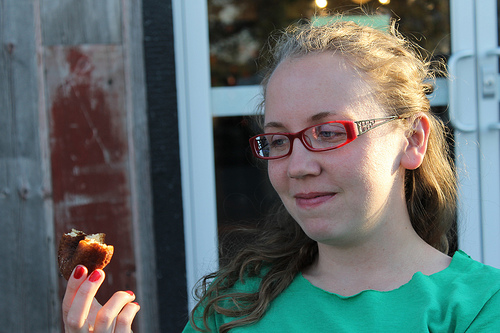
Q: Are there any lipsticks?
A: No, there are no lipsticks.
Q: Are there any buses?
A: No, there are no buses.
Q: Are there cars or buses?
A: No, there are no buses or cars.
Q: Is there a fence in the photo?
A: No, there are no fences.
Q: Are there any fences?
A: No, there are no fences.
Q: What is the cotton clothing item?
A: The clothing item is a shirt.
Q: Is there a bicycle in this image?
A: No, there are no bicycles.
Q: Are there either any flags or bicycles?
A: No, there are no bicycles or flags.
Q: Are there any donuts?
A: Yes, there is a donut.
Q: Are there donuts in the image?
A: Yes, there is a donut.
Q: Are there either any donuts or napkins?
A: Yes, there is a donut.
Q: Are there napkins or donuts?
A: Yes, there is a donut.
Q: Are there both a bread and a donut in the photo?
A: No, there is a donut but no breads.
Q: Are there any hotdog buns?
A: No, there are no hotdog buns.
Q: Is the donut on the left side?
A: Yes, the donut is on the left of the image.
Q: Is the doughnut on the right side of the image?
A: No, the doughnut is on the left of the image.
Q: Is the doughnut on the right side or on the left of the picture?
A: The doughnut is on the left of the image.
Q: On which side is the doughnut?
A: The doughnut is on the left of the image.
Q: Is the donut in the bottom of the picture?
A: Yes, the donut is in the bottom of the image.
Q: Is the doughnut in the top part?
A: No, the doughnut is in the bottom of the image.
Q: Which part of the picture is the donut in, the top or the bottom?
A: The donut is in the bottom of the image.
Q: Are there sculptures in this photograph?
A: No, there are no sculptures.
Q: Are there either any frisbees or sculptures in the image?
A: No, there are no sculptures or frisbees.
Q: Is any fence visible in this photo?
A: No, there are no fences.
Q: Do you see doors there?
A: Yes, there is a door.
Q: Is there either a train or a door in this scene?
A: Yes, there is a door.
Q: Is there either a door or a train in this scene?
A: Yes, there is a door.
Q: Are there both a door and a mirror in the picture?
A: No, there is a door but no mirrors.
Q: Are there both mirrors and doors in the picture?
A: No, there is a door but no mirrors.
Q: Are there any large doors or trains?
A: Yes, there is a large door.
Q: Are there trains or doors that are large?
A: Yes, the door is large.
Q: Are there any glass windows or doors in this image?
A: Yes, there is a glass door.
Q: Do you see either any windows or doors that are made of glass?
A: Yes, the door is made of glass.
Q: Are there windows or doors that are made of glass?
A: Yes, the door is made of glass.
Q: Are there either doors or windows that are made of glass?
A: Yes, the door is made of glass.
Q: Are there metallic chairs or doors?
A: Yes, there is a metal door.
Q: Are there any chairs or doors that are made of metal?
A: Yes, the door is made of metal.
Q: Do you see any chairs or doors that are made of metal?
A: Yes, the door is made of metal.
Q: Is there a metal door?
A: Yes, there is a door that is made of metal.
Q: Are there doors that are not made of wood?
A: Yes, there is a door that is made of metal.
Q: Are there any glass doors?
A: Yes, there is a door that is made of glass.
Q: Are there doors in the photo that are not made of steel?
A: Yes, there is a door that is made of glass.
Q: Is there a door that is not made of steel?
A: Yes, there is a door that is made of glass.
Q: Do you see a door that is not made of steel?
A: Yes, there is a door that is made of glass.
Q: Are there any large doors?
A: Yes, there is a large door.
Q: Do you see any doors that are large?
A: Yes, there is a door that is large.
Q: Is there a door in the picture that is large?
A: Yes, there is a door that is large.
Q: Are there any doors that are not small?
A: Yes, there is a large door.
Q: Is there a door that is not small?
A: Yes, there is a large door.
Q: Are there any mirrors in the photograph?
A: No, there are no mirrors.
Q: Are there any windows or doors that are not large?
A: No, there is a door but it is large.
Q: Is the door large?
A: Yes, the door is large.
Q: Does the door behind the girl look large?
A: Yes, the door is large.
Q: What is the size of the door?
A: The door is large.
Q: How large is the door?
A: The door is large.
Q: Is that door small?
A: No, the door is large.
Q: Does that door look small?
A: No, the door is large.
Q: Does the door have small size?
A: No, the door is large.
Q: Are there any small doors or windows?
A: No, there is a door but it is large.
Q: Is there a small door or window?
A: No, there is a door but it is large.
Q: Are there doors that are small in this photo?
A: No, there is a door but it is large.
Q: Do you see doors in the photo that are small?
A: No, there is a door but it is large.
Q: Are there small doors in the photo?
A: No, there is a door but it is large.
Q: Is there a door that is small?
A: No, there is a door but it is large.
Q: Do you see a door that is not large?
A: No, there is a door but it is large.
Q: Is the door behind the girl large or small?
A: The door is large.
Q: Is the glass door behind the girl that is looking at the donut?
A: Yes, the door is behind the girl.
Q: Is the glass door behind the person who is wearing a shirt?
A: Yes, the door is behind the girl.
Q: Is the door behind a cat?
A: No, the door is behind the girl.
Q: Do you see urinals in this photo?
A: No, there are no urinals.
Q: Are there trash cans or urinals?
A: No, there are no urinals or trash cans.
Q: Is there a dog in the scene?
A: No, there are no dogs.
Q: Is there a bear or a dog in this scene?
A: No, there are no dogs or bears.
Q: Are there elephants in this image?
A: No, there are no elephants.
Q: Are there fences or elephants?
A: No, there are no elephants or fences.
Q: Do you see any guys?
A: No, there are no guys.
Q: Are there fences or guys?
A: No, there are no guys or fences.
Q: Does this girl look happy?
A: Yes, the girl is happy.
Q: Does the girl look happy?
A: Yes, the girl is happy.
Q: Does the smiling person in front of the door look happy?
A: Yes, the girl is happy.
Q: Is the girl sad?
A: No, the girl is happy.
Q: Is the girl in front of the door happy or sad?
A: The girl is happy.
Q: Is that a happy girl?
A: Yes, that is a happy girl.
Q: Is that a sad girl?
A: No, that is a happy girl.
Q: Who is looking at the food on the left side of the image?
A: The girl is looking at the donut.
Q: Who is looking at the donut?
A: The girl is looking at the donut.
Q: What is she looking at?
A: The girl is looking at the doughnut.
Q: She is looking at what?
A: The girl is looking at the doughnut.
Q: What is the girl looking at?
A: The girl is looking at the doughnut.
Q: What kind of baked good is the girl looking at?
A: The girl is looking at the donut.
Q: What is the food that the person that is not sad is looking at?
A: The food is a donut.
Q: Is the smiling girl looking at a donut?
A: Yes, the girl is looking at a donut.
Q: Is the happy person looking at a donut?
A: Yes, the girl is looking at a donut.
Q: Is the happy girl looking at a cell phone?
A: No, the girl is looking at a donut.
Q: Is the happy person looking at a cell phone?
A: No, the girl is looking at a donut.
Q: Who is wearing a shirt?
A: The girl is wearing a shirt.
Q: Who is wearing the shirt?
A: The girl is wearing a shirt.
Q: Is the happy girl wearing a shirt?
A: Yes, the girl is wearing a shirt.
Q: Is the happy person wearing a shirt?
A: Yes, the girl is wearing a shirt.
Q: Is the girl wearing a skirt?
A: No, the girl is wearing a shirt.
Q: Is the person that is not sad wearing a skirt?
A: No, the girl is wearing a shirt.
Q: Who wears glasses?
A: The girl wears glasses.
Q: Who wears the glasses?
A: The girl wears glasses.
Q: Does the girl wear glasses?
A: Yes, the girl wears glasses.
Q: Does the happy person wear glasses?
A: Yes, the girl wears glasses.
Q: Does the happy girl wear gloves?
A: No, the girl wears glasses.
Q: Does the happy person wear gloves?
A: No, the girl wears glasses.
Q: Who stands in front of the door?
A: The girl stands in front of the door.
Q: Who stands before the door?
A: The girl stands in front of the door.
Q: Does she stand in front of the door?
A: Yes, the girl stands in front of the door.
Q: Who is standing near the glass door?
A: The girl is standing near the door.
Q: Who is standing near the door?
A: The girl is standing near the door.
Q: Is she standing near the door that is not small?
A: Yes, the girl is standing near the door.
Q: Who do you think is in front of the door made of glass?
A: The girl is in front of the door.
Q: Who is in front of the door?
A: The girl is in front of the door.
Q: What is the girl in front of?
A: The girl is in front of the door.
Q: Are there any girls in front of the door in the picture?
A: Yes, there is a girl in front of the door.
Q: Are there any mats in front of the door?
A: No, there is a girl in front of the door.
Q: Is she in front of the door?
A: Yes, the girl is in front of the door.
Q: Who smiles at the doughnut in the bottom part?
A: The girl smiles at the doughnut.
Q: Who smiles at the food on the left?
A: The girl smiles at the doughnut.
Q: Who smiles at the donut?
A: The girl smiles at the doughnut.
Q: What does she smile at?
A: The girl smiles at the doughnut.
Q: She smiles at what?
A: The girl smiles at the doughnut.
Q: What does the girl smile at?
A: The girl smiles at the doughnut.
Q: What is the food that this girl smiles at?
A: The food is a donut.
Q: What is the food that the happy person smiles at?
A: The food is a donut.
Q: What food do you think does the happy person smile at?
A: The girl smiles at the doughnut.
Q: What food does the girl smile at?
A: The girl smiles at the doughnut.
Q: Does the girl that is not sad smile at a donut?
A: Yes, the girl smiles at a donut.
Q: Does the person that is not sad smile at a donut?
A: Yes, the girl smiles at a donut.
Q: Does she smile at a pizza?
A: No, the girl smiles at a donut.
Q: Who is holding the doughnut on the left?
A: The girl is holding the doughnut.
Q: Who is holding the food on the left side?
A: The girl is holding the doughnut.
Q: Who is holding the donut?
A: The girl is holding the doughnut.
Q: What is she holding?
A: The girl is holding the donut.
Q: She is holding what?
A: The girl is holding the donut.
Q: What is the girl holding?
A: The girl is holding the donut.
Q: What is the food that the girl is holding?
A: The food is a donut.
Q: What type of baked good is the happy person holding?
A: The girl is holding the doughnut.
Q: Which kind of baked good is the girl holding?
A: The girl is holding the doughnut.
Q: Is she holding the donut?
A: Yes, the girl is holding the donut.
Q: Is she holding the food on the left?
A: Yes, the girl is holding the donut.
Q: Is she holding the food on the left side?
A: Yes, the girl is holding the donut.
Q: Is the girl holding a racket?
A: No, the girl is holding the donut.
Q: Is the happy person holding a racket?
A: No, the girl is holding the donut.